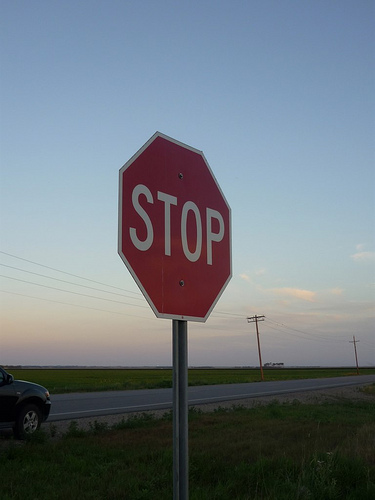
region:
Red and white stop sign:
[110, 128, 237, 328]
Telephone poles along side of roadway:
[243, 307, 371, 380]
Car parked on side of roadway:
[2, 347, 58, 446]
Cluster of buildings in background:
[261, 355, 285, 370]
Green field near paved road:
[1, 365, 373, 393]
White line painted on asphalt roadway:
[46, 378, 374, 418]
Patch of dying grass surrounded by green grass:
[72, 420, 372, 467]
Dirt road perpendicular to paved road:
[288, 382, 372, 407]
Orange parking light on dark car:
[40, 386, 52, 402]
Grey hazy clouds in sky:
[43, 309, 368, 364]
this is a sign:
[95, 125, 280, 351]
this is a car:
[1, 367, 55, 447]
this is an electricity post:
[246, 295, 284, 392]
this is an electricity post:
[342, 317, 367, 396]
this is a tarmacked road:
[47, 344, 373, 428]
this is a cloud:
[267, 280, 309, 321]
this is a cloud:
[55, 284, 111, 357]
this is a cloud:
[222, 316, 259, 363]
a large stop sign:
[72, 128, 253, 498]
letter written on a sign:
[101, 126, 241, 325]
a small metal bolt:
[169, 272, 193, 296]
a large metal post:
[126, 305, 231, 494]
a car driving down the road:
[0, 354, 63, 440]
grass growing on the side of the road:
[237, 418, 304, 480]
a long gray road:
[211, 378, 333, 402]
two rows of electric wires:
[236, 298, 373, 389]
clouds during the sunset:
[60, 298, 160, 376]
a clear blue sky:
[234, 123, 362, 215]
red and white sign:
[120, 124, 261, 370]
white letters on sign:
[138, 115, 232, 343]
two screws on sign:
[175, 160, 197, 298]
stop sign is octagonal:
[86, 88, 263, 325]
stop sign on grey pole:
[157, 317, 214, 486]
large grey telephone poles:
[242, 318, 363, 384]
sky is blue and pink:
[306, 254, 366, 360]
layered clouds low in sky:
[268, 281, 360, 361]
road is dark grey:
[190, 372, 302, 406]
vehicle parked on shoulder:
[2, 350, 53, 434]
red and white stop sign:
[113, 127, 242, 327]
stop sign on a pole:
[110, 125, 229, 498]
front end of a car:
[0, 361, 62, 439]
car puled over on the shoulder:
[0, 361, 58, 441]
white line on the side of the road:
[50, 380, 374, 421]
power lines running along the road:
[0, 247, 373, 382]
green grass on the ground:
[0, 396, 374, 498]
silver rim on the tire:
[16, 406, 44, 436]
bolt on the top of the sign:
[177, 171, 185, 179]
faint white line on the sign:
[155, 258, 172, 312]